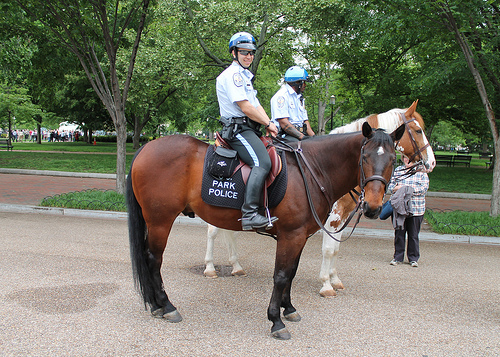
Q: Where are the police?
A: At the park.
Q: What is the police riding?
A: Horses.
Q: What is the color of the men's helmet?
A: Blue.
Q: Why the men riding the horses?
A: To patrol around.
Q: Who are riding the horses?
A: The men.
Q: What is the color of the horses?
A: Brown, black and white.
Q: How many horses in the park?
A: Two.